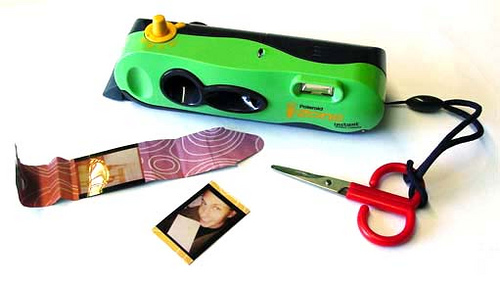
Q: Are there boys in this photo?
A: No, there are no boys.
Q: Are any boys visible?
A: No, there are no boys.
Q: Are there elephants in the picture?
A: No, there are no elephants.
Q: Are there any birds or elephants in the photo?
A: No, there are no elephants or birds.